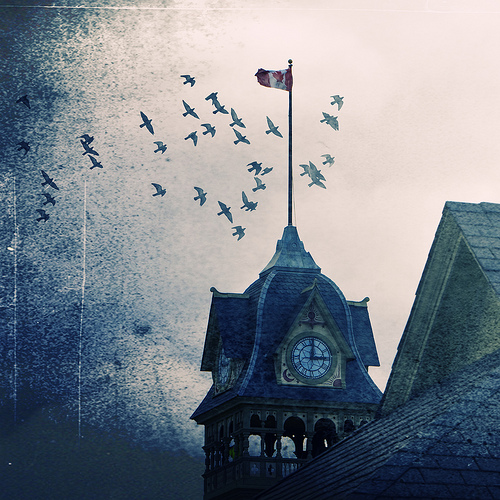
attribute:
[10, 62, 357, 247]
birds — flock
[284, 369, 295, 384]
moon — decoration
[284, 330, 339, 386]
clock — round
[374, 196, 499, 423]
roof — peaked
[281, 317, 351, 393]
clock — sunlit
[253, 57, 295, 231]
flag — Canadian, tall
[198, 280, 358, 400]
clocks — big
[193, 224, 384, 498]
clock tower — old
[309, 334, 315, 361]
hand — black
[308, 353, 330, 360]
hand — black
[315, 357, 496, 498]
roof — gray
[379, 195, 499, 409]
roof — triangular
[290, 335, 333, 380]
clock — time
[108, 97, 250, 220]
birds — flock, flying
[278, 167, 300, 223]
pole — metal, flag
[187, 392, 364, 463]
windows — arched